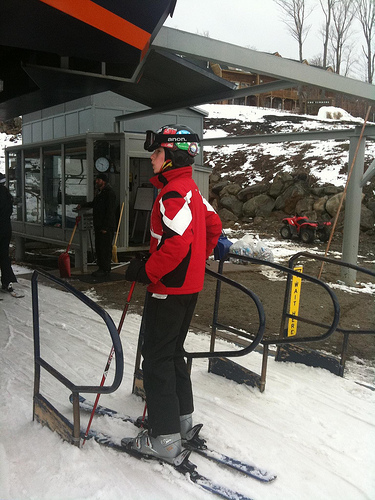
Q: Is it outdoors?
A: Yes, it is outdoors.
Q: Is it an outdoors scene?
A: Yes, it is outdoors.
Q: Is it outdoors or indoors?
A: It is outdoors.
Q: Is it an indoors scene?
A: No, it is outdoors.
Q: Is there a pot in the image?
A: No, there are no pots.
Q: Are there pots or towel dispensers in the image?
A: No, there are no pots or towel dispensers.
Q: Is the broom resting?
A: Yes, the broom is resting.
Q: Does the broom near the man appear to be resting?
A: Yes, the broom is resting.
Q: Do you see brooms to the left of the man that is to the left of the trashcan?
A: Yes, there is a broom to the left of the man.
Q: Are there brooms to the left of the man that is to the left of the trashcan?
A: Yes, there is a broom to the left of the man.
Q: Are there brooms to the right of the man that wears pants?
A: No, the broom is to the left of the man.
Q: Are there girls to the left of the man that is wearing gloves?
A: No, there is a broom to the left of the man.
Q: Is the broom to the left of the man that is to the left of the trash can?
A: Yes, the broom is to the left of the man.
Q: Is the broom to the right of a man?
A: No, the broom is to the left of a man.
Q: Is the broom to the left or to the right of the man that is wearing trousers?
A: The broom is to the left of the man.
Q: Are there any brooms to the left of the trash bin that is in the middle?
A: Yes, there is a broom to the left of the trashcan.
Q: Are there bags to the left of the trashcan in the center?
A: No, there is a broom to the left of the garbage bin.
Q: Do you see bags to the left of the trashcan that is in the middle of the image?
A: No, there is a broom to the left of the garbage bin.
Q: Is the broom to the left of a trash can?
A: Yes, the broom is to the left of a trash can.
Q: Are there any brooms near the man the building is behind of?
A: Yes, there is a broom near the man.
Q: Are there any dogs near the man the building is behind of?
A: No, there is a broom near the man.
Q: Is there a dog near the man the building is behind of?
A: No, there is a broom near the man.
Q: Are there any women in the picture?
A: No, there are no women.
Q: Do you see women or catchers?
A: No, there are no women or catchers.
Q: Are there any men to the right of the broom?
A: Yes, there is a man to the right of the broom.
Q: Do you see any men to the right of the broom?
A: Yes, there is a man to the right of the broom.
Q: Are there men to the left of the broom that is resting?
A: No, the man is to the right of the broom.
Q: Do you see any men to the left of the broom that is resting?
A: No, the man is to the right of the broom.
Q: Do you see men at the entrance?
A: Yes, there is a man at the entrance.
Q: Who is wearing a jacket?
A: The man is wearing a jacket.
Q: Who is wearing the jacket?
A: The man is wearing a jacket.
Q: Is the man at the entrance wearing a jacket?
A: Yes, the man is wearing a jacket.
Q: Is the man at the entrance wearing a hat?
A: No, the man is wearing a jacket.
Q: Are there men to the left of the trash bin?
A: Yes, there is a man to the left of the trash bin.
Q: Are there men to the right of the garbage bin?
A: No, the man is to the left of the garbage bin.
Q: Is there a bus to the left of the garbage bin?
A: No, there is a man to the left of the garbage bin.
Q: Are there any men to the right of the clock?
A: Yes, there is a man to the right of the clock.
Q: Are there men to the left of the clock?
A: No, the man is to the right of the clock.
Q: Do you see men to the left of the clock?
A: No, the man is to the right of the clock.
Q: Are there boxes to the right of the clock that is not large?
A: No, there is a man to the right of the clock.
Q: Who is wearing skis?
A: The man is wearing skis.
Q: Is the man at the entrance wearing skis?
A: Yes, the man is wearing skis.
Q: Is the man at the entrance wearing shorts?
A: No, the man is wearing skis.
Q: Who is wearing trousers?
A: The man is wearing trousers.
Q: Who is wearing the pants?
A: The man is wearing trousers.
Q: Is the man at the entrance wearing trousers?
A: Yes, the man is wearing trousers.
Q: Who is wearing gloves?
A: The man is wearing gloves.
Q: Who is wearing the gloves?
A: The man is wearing gloves.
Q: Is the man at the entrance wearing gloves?
A: Yes, the man is wearing gloves.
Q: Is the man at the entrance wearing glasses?
A: No, the man is wearing gloves.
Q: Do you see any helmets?
A: Yes, there is a helmet.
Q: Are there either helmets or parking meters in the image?
A: Yes, there is a helmet.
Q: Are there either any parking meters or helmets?
A: Yes, there is a helmet.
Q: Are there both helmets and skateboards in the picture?
A: No, there is a helmet but no skateboards.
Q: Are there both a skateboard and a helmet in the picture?
A: No, there is a helmet but no skateboards.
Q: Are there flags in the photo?
A: No, there are no flags.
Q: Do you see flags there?
A: No, there are no flags.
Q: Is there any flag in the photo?
A: No, there are no flags.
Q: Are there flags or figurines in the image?
A: No, there are no flags or figurines.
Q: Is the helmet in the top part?
A: Yes, the helmet is in the top of the image.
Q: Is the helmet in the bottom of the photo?
A: No, the helmet is in the top of the image.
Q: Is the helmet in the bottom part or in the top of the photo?
A: The helmet is in the top of the image.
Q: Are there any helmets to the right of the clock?
A: Yes, there is a helmet to the right of the clock.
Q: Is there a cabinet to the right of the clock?
A: No, there is a helmet to the right of the clock.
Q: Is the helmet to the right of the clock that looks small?
A: Yes, the helmet is to the right of the clock.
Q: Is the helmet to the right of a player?
A: No, the helmet is to the right of the clock.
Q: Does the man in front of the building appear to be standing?
A: Yes, the man is standing.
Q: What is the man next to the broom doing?
A: The man is standing.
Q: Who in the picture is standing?
A: The man is standing.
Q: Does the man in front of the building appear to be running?
A: No, the man is standing.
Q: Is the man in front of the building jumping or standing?
A: The man is standing.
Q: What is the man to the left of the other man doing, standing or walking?
A: The man is standing.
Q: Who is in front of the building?
A: The man is in front of the building.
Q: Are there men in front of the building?
A: Yes, there is a man in front of the building.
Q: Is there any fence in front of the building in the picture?
A: No, there is a man in front of the building.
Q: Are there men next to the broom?
A: Yes, there is a man next to the broom.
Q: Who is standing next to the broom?
A: The man is standing next to the broom.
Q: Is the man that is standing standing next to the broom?
A: Yes, the man is standing next to the broom.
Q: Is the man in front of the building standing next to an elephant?
A: No, the man is standing next to the broom.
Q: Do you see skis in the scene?
A: Yes, there are skis.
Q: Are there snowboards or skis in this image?
A: Yes, there are skis.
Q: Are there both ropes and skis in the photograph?
A: No, there are skis but no ropes.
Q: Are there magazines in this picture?
A: No, there are no magazines.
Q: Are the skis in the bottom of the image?
A: Yes, the skis are in the bottom of the image.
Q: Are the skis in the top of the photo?
A: No, the skis are in the bottom of the image.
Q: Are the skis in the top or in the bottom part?
A: The skis are in the bottom of the image.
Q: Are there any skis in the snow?
A: Yes, there are skis in the snow.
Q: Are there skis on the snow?
A: Yes, there are skis on the snow.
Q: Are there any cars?
A: No, there are no cars.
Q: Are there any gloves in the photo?
A: Yes, there are gloves.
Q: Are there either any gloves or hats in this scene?
A: Yes, there are gloves.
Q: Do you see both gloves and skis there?
A: Yes, there are both gloves and a ski.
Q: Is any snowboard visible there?
A: No, there are no snowboards.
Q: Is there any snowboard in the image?
A: No, there are no snowboards.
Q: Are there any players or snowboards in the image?
A: No, there are no snowboards or players.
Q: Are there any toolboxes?
A: No, there are no toolboxes.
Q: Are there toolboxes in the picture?
A: No, there are no toolboxes.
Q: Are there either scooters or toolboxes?
A: No, there are no toolboxes or scooters.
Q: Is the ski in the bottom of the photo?
A: Yes, the ski is in the bottom of the image.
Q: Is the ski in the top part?
A: No, the ski is in the bottom of the image.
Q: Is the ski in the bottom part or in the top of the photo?
A: The ski is in the bottom of the image.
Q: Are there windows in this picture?
A: Yes, there are windows.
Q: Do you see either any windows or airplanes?
A: Yes, there are windows.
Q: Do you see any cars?
A: No, there are no cars.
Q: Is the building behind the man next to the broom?
A: Yes, the building is behind the man.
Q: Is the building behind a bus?
A: No, the building is behind the man.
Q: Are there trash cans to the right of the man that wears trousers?
A: Yes, there is a trash can to the right of the man.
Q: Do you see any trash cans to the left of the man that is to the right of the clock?
A: No, the trash can is to the right of the man.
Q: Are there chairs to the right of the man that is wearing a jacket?
A: No, there is a trash can to the right of the man.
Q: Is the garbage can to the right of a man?
A: Yes, the garbage can is to the right of a man.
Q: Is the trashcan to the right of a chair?
A: No, the trashcan is to the right of a man.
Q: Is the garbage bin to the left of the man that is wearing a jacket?
A: No, the garbage bin is to the right of the man.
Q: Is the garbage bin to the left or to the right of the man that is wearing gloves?
A: The garbage bin is to the right of the man.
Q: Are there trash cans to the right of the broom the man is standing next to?
A: Yes, there is a trash can to the right of the broom.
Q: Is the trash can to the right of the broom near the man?
A: Yes, the trash can is to the right of the broom.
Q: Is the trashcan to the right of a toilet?
A: No, the trashcan is to the right of the broom.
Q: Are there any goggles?
A: Yes, there are goggles.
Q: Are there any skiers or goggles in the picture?
A: Yes, there are goggles.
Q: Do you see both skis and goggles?
A: Yes, there are both goggles and a ski.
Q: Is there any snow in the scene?
A: Yes, there is snow.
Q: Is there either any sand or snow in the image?
A: Yes, there is snow.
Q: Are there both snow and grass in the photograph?
A: No, there is snow but no grass.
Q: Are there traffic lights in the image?
A: No, there are no traffic lights.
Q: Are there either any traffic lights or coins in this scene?
A: No, there are no traffic lights or coins.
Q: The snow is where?
A: The snow is on the ground.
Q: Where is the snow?
A: The snow is on the ground.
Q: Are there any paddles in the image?
A: No, there are no paddles.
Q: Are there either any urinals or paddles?
A: No, there are no paddles or urinals.